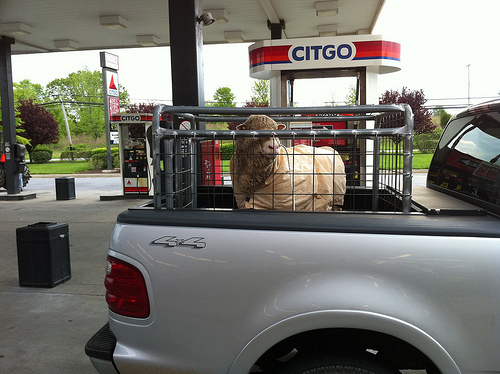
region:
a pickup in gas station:
[0, 2, 497, 370]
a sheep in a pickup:
[80, 84, 499, 371]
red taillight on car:
[91, 246, 163, 326]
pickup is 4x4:
[133, 220, 221, 265]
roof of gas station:
[1, 0, 392, 68]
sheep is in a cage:
[143, 90, 418, 207]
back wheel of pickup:
[243, 319, 438, 371]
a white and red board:
[95, 50, 128, 173]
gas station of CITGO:
[243, 28, 407, 77]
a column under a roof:
[163, 3, 210, 103]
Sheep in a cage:
[201, 80, 367, 193]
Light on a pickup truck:
[91, 245, 161, 318]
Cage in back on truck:
[146, 97, 453, 204]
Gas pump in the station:
[102, 95, 154, 211]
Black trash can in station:
[12, 218, 73, 295]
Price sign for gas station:
[98, 53, 128, 167]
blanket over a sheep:
[283, 141, 345, 203]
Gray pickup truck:
[99, 220, 481, 372]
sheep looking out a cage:
[226, 108, 281, 161]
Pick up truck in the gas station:
[115, 153, 390, 368]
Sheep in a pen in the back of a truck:
[145, 102, 417, 209]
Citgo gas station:
[0, 0, 403, 204]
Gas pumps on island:
[108, 108, 157, 199]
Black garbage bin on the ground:
[13, 213, 71, 289]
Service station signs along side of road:
[97, 47, 122, 173]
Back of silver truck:
[83, 100, 498, 372]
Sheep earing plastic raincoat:
[228, 113, 345, 214]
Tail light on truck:
[101, 251, 151, 322]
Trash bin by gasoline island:
[52, 173, 77, 202]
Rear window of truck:
[425, 98, 498, 210]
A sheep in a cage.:
[137, 99, 424, 206]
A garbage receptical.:
[9, 194, 87, 304]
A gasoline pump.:
[91, 104, 166, 197]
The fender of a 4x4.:
[85, 209, 498, 366]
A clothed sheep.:
[141, 94, 455, 228]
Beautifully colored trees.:
[13, 60, 103, 143]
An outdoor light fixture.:
[176, 8, 265, 49]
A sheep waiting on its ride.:
[86, 91, 498, 368]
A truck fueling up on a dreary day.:
[7, 5, 498, 371]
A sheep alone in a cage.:
[151, 101, 430, 250]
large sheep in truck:
[234, 116, 354, 193]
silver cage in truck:
[225, 117, 333, 194]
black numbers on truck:
[143, 233, 238, 279]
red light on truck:
[107, 255, 184, 362]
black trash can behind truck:
[20, 222, 72, 300]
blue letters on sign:
[286, 50, 376, 67]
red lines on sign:
[260, 50, 298, 65]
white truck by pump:
[143, 187, 389, 372]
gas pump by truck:
[266, 59, 406, 119]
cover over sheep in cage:
[186, 105, 363, 210]